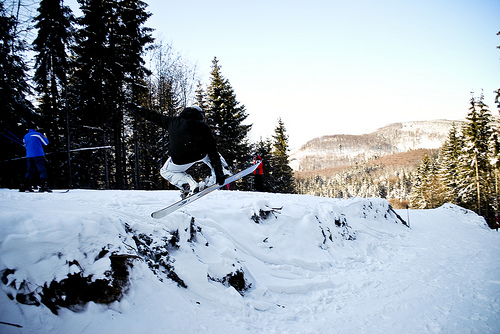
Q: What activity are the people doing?
A: Snowboarding.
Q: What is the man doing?
A: Snowboarding.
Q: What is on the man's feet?
A: A snowboard.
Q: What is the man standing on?
A: Air.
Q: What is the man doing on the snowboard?
A: Performing tricks.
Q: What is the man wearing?
A: A black sweater and white ski pants.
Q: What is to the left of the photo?
A: A man standing in the snow.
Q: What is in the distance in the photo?
A: Snow capped hills.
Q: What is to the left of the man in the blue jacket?
A: Pine trees.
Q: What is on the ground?
A: Snow.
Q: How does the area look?
A: White.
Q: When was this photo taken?
A: During winter.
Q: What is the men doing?
A: Snowboarding.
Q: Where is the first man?
A: In the air.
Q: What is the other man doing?
A: Standing.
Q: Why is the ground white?
A: Snow.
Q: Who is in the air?
A: The first man.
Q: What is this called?
A: A jump.